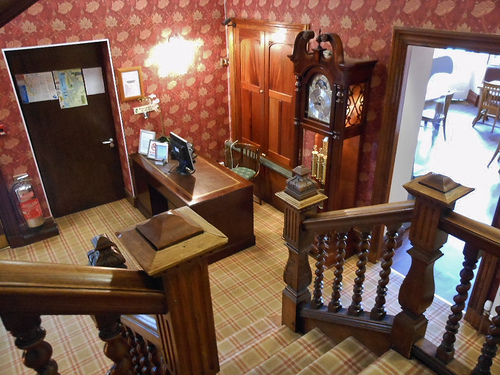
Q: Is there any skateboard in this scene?
A: No, there are no skateboards.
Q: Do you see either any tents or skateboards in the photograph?
A: No, there are no skateboards or tents.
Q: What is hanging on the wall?
A: The frame is hanging on the wall.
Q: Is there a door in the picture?
A: Yes, there is a door.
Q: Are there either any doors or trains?
A: Yes, there is a door.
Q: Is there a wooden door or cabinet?
A: Yes, there is a wood door.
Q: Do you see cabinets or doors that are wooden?
A: Yes, the door is wooden.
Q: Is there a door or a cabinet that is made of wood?
A: Yes, the door is made of wood.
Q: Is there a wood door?
A: Yes, there is a door that is made of wood.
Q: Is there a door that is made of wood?
A: Yes, there is a door that is made of wood.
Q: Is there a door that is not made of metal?
A: Yes, there is a door that is made of wood.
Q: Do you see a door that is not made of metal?
A: Yes, there is a door that is made of wood.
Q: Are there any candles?
A: No, there are no candles.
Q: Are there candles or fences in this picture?
A: No, there are no candles or fences.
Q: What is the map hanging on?
A: The map is hanging on the door.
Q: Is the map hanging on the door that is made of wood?
A: Yes, the map is hanging on the door.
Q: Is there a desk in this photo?
A: Yes, there is a desk.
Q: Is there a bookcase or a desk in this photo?
A: Yes, there is a desk.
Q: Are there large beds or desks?
A: Yes, there is a large desk.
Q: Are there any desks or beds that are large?
A: Yes, the desk is large.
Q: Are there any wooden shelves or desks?
A: Yes, there is a wood desk.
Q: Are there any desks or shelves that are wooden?
A: Yes, the desk is wooden.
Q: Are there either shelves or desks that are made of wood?
A: Yes, the desk is made of wood.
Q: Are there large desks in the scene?
A: Yes, there is a large desk.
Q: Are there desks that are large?
A: Yes, there is a desk that is large.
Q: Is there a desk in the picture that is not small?
A: Yes, there is a large desk.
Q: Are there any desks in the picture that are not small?
A: Yes, there is a large desk.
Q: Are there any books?
A: No, there are no books.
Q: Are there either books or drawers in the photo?
A: No, there are no books or drawers.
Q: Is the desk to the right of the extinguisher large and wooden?
A: Yes, the desk is large and wooden.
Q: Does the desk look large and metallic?
A: No, the desk is large but wooden.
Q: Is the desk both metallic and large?
A: No, the desk is large but wooden.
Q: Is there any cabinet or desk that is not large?
A: No, there is a desk but it is large.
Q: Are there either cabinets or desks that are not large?
A: No, there is a desk but it is large.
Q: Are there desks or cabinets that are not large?
A: No, there is a desk but it is large.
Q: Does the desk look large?
A: Yes, the desk is large.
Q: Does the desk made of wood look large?
A: Yes, the desk is large.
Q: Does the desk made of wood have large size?
A: Yes, the desk is large.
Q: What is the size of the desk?
A: The desk is large.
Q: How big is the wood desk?
A: The desk is large.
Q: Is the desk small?
A: No, the desk is large.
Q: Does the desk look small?
A: No, the desk is large.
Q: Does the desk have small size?
A: No, the desk is large.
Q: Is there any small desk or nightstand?
A: No, there is a desk but it is large.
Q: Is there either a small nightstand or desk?
A: No, there is a desk but it is large.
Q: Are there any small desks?
A: No, there is a desk but it is large.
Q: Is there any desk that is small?
A: No, there is a desk but it is large.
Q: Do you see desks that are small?
A: No, there is a desk but it is large.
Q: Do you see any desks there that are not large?
A: No, there is a desk but it is large.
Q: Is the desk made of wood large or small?
A: The desk is large.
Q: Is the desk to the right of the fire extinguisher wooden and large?
A: Yes, the desk is wooden and large.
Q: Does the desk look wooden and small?
A: No, the desk is wooden but large.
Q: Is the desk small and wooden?
A: No, the desk is wooden but large.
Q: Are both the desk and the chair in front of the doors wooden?
A: Yes, both the desk and the chair are wooden.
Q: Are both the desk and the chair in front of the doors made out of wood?
A: Yes, both the desk and the chair are made of wood.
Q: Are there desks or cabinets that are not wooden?
A: No, there is a desk but it is wooden.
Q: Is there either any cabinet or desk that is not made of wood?
A: No, there is a desk but it is made of wood.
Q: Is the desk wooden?
A: Yes, the desk is wooden.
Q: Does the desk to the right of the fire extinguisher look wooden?
A: Yes, the desk is wooden.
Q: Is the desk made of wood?
A: Yes, the desk is made of wood.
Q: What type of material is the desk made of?
A: The desk is made of wood.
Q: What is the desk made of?
A: The desk is made of wood.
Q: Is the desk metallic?
A: No, the desk is wooden.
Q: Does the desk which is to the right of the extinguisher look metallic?
A: No, the desk is wooden.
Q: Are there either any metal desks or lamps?
A: No, there is a desk but it is wooden.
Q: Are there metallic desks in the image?
A: No, there is a desk but it is wooden.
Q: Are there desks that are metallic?
A: No, there is a desk but it is wooden.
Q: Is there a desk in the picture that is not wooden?
A: No, there is a desk but it is wooden.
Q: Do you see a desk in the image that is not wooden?
A: No, there is a desk but it is wooden.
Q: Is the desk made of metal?
A: No, the desk is made of wood.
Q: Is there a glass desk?
A: No, there is a desk but it is made of wood.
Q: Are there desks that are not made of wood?
A: No, there is a desk but it is made of wood.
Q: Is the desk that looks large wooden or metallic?
A: The desk is wooden.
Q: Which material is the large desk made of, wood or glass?
A: The desk is made of wood.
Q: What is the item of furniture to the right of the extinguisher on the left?
A: The piece of furniture is a desk.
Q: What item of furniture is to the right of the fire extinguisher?
A: The piece of furniture is a desk.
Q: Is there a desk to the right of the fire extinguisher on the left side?
A: Yes, there is a desk to the right of the fire extinguisher.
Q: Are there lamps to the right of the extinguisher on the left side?
A: No, there is a desk to the right of the extinguisher.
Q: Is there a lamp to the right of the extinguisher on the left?
A: No, there is a desk to the right of the extinguisher.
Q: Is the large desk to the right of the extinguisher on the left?
A: Yes, the desk is to the right of the fire extinguisher.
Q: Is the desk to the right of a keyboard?
A: No, the desk is to the right of the fire extinguisher.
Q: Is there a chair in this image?
A: Yes, there is a chair.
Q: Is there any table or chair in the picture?
A: Yes, there is a chair.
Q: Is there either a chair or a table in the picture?
A: Yes, there is a chair.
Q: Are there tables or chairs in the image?
A: Yes, there is a chair.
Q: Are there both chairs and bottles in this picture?
A: No, there is a chair but no bottles.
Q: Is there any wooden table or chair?
A: Yes, there is a wood chair.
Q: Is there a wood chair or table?
A: Yes, there is a wood chair.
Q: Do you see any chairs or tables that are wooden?
A: Yes, the chair is wooden.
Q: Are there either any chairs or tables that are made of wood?
A: Yes, the chair is made of wood.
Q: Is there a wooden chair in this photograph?
A: Yes, there is a wood chair.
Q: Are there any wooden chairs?
A: Yes, there is a wood chair.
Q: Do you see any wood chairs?
A: Yes, there is a wood chair.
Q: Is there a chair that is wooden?
A: Yes, there is a chair that is wooden.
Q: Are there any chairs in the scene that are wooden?
A: Yes, there is a chair that is wooden.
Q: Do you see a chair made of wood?
A: Yes, there is a chair that is made of wood.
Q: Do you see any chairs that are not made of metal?
A: Yes, there is a chair that is made of wood.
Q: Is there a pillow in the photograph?
A: No, there are no pillows.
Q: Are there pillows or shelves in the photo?
A: No, there are no pillows or shelves.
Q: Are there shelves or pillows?
A: No, there are no pillows or shelves.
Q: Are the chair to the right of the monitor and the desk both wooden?
A: Yes, both the chair and the desk are wooden.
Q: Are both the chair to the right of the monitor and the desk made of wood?
A: Yes, both the chair and the desk are made of wood.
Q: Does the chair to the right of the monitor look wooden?
A: Yes, the chair is wooden.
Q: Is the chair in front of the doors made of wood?
A: Yes, the chair is made of wood.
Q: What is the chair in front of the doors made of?
A: The chair is made of wood.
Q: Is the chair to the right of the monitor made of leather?
A: No, the chair is made of wood.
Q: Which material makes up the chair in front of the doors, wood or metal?
A: The chair is made of wood.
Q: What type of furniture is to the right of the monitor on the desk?
A: The piece of furniture is a chair.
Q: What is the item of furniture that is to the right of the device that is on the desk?
A: The piece of furniture is a chair.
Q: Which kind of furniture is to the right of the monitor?
A: The piece of furniture is a chair.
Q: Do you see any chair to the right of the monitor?
A: Yes, there is a chair to the right of the monitor.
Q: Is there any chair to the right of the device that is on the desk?
A: Yes, there is a chair to the right of the monitor.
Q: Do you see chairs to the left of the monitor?
A: No, the chair is to the right of the monitor.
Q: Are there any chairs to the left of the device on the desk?
A: No, the chair is to the right of the monitor.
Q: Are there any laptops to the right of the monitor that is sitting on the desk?
A: No, there is a chair to the right of the monitor.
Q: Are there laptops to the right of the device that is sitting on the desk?
A: No, there is a chair to the right of the monitor.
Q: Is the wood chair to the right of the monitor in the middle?
A: Yes, the chair is to the right of the monitor.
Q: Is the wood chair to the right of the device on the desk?
A: Yes, the chair is to the right of the monitor.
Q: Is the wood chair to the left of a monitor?
A: No, the chair is to the right of a monitor.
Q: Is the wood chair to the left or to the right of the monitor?
A: The chair is to the right of the monitor.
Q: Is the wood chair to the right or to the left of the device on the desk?
A: The chair is to the right of the monitor.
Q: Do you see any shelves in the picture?
A: No, there are no shelves.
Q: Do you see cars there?
A: No, there are no cars.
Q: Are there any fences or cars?
A: No, there are no cars or fences.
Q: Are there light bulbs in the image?
A: No, there are no light bulbs.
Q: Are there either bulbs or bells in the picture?
A: No, there are no bulbs or bells.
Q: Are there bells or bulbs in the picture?
A: No, there are no bulbs or bells.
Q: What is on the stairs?
A: The rug is on the stairs.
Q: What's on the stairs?
A: The rug is on the stairs.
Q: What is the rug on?
A: The rug is on the stairs.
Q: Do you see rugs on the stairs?
A: Yes, there is a rug on the stairs.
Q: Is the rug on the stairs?
A: Yes, the rug is on the stairs.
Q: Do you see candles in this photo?
A: No, there are no candles.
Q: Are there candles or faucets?
A: No, there are no candles or faucets.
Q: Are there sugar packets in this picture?
A: No, there are no sugar packets.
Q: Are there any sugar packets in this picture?
A: No, there are no sugar packets.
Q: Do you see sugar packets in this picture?
A: No, there are no sugar packets.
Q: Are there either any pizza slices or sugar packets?
A: No, there are no sugar packets or pizza slices.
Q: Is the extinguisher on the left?
A: Yes, the extinguisher is on the left of the image.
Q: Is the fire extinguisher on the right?
A: No, the fire extinguisher is on the left of the image.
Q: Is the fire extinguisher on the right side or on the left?
A: The fire extinguisher is on the left of the image.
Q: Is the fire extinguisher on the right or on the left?
A: The fire extinguisher is on the left of the image.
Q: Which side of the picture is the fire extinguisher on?
A: The fire extinguisher is on the left of the image.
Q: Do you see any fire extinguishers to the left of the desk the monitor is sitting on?
A: Yes, there is a fire extinguisher to the left of the desk.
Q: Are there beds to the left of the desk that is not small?
A: No, there is a fire extinguisher to the left of the desk.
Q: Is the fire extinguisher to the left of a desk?
A: Yes, the fire extinguisher is to the left of a desk.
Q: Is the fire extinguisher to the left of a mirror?
A: No, the fire extinguisher is to the left of a desk.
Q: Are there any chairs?
A: Yes, there is a chair.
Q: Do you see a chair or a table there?
A: Yes, there is a chair.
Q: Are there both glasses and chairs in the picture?
A: No, there is a chair but no glasses.